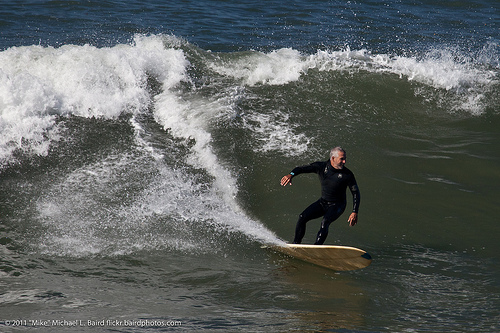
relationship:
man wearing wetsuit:
[277, 142, 368, 249] [289, 159, 368, 246]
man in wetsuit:
[277, 142, 368, 249] [289, 159, 368, 246]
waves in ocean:
[4, 30, 500, 210] [2, 0, 500, 332]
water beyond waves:
[2, 2, 500, 61] [4, 30, 500, 210]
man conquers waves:
[277, 142, 368, 249] [4, 30, 500, 210]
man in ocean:
[277, 142, 368, 249] [2, 0, 500, 332]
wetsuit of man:
[289, 159, 368, 246] [277, 142, 368, 249]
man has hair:
[277, 142, 368, 249] [329, 143, 345, 153]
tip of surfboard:
[360, 249, 373, 262] [272, 239, 376, 280]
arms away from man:
[345, 176, 360, 226] [277, 142, 368, 249]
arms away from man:
[279, 159, 320, 190] [277, 142, 368, 249]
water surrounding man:
[1, 205, 500, 332] [277, 142, 368, 249]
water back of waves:
[2, 2, 500, 61] [4, 30, 500, 210]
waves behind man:
[4, 30, 500, 210] [277, 142, 368, 249]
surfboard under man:
[272, 239, 376, 280] [277, 142, 368, 249]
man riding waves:
[277, 142, 368, 249] [4, 30, 500, 210]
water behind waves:
[2, 2, 500, 61] [4, 30, 500, 210]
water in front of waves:
[1, 205, 500, 332] [4, 30, 500, 210]